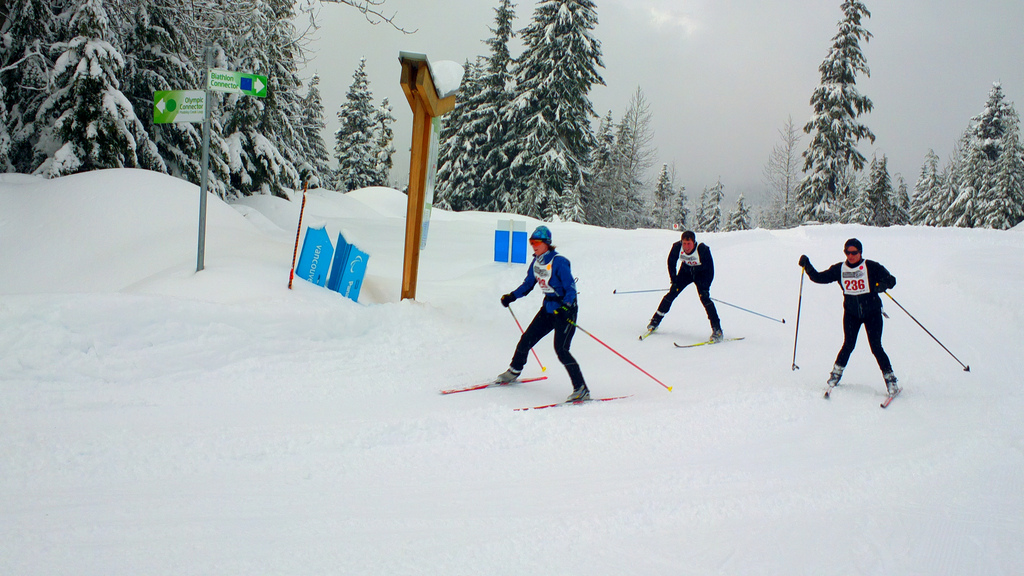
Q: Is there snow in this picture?
A: Yes, there is snow.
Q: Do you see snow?
A: Yes, there is snow.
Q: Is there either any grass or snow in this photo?
A: Yes, there is snow.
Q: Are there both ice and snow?
A: No, there is snow but no ice.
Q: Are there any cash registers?
A: No, there are no cash registers.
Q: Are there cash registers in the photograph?
A: No, there are no cash registers.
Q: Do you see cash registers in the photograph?
A: No, there are no cash registers.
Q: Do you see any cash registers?
A: No, there are no cash registers.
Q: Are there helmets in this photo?
A: No, there are no helmets.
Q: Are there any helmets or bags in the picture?
A: No, there are no helmets or bags.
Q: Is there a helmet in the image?
A: No, there are no helmets.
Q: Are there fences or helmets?
A: No, there are no helmets or fences.